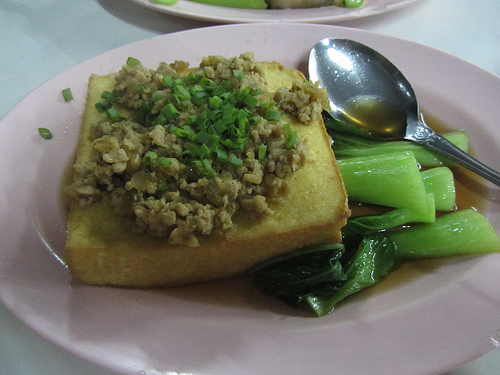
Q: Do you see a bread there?
A: Yes, there is a bread.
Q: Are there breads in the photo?
A: Yes, there is a bread.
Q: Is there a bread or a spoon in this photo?
A: Yes, there is a bread.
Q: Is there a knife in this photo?
A: No, there are no knives.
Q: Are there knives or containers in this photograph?
A: No, there are no knives or containers.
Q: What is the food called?
A: The food is a bread.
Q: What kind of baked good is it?
A: The food is a bread.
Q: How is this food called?
A: This is a bread.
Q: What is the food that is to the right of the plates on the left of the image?
A: The food is a bread.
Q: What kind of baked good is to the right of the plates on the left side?
A: The food is a bread.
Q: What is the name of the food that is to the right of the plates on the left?
A: The food is a bread.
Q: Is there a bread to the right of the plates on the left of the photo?
A: Yes, there is a bread to the right of the plates.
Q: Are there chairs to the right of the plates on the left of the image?
A: No, there is a bread to the right of the plates.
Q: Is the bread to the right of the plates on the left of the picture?
A: Yes, the bread is to the right of the plates.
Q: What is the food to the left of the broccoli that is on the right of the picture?
A: The food is a bread.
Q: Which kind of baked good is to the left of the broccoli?
A: The food is a bread.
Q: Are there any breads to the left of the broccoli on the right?
A: Yes, there is a bread to the left of the broccoli.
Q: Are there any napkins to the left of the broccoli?
A: No, there is a bread to the left of the broccoli.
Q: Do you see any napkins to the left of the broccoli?
A: No, there is a bread to the left of the broccoli.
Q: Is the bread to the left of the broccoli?
A: Yes, the bread is to the left of the broccoli.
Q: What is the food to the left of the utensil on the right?
A: The food is a bread.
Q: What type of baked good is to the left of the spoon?
A: The food is a bread.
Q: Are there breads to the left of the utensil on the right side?
A: Yes, there is a bread to the left of the spoon.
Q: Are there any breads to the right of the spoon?
A: No, the bread is to the left of the spoon.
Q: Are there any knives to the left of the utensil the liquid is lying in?
A: No, there is a bread to the left of the spoon.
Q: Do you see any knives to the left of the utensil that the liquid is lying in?
A: No, there is a bread to the left of the spoon.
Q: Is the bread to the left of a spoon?
A: Yes, the bread is to the left of a spoon.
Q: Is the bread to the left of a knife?
A: No, the bread is to the left of a spoon.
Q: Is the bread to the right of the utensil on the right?
A: No, the bread is to the left of the spoon.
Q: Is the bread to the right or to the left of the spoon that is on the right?
A: The bread is to the left of the spoon.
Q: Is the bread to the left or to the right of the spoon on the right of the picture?
A: The bread is to the left of the spoon.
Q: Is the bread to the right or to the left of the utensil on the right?
A: The bread is to the left of the spoon.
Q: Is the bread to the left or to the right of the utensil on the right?
A: The bread is to the left of the spoon.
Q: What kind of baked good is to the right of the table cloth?
A: The food is a bread.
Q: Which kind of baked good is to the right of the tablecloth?
A: The food is a bread.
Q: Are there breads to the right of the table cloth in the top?
A: Yes, there is a bread to the right of the tablecloth.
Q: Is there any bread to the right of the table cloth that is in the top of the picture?
A: Yes, there is a bread to the right of the tablecloth.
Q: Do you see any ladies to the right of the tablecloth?
A: No, there is a bread to the right of the tablecloth.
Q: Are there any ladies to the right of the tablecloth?
A: No, there is a bread to the right of the tablecloth.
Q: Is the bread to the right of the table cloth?
A: Yes, the bread is to the right of the table cloth.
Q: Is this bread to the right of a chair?
A: No, the bread is to the right of the table cloth.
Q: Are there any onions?
A: Yes, there are onions.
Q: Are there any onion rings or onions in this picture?
A: Yes, there are onions.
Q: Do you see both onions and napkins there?
A: No, there are onions but no napkins.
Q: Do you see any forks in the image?
A: No, there are no forks.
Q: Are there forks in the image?
A: No, there are no forks.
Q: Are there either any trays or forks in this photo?
A: No, there are no forks or trays.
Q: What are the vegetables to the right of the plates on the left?
A: The vegetables are onions.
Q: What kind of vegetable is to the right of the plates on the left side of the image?
A: The vegetables are onions.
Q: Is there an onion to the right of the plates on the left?
A: Yes, there are onions to the right of the plates.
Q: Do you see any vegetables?
A: Yes, there are vegetables.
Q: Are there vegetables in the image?
A: Yes, there are vegetables.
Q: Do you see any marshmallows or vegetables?
A: Yes, there are vegetables.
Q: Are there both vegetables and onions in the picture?
A: Yes, there are both vegetables and an onion.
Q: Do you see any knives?
A: No, there are no knives.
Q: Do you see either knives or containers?
A: No, there are no knives or containers.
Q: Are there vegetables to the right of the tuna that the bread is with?
A: Yes, there are vegetables to the right of the tuna.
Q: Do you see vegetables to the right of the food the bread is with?
A: Yes, there are vegetables to the right of the tuna.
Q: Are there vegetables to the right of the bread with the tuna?
A: Yes, there are vegetables to the right of the bread.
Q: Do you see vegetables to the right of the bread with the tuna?
A: Yes, there are vegetables to the right of the bread.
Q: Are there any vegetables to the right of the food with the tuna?
A: Yes, there are vegetables to the right of the bread.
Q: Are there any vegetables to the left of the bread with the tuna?
A: No, the vegetables are to the right of the bread.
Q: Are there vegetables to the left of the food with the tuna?
A: No, the vegetables are to the right of the bread.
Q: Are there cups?
A: No, there are no cups.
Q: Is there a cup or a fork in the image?
A: No, there are no cups or forks.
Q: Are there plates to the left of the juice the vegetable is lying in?
A: Yes, there are plates to the left of the juice.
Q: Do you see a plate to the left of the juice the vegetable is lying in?
A: Yes, there are plates to the left of the juice.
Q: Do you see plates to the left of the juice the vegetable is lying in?
A: Yes, there are plates to the left of the juice.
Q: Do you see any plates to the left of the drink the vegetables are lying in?
A: Yes, there are plates to the left of the juice.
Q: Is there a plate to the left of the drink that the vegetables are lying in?
A: Yes, there are plates to the left of the juice.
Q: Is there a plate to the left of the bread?
A: Yes, there are plates to the left of the bread.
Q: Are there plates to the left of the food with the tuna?
A: Yes, there are plates to the left of the bread.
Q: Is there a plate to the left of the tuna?
A: Yes, there are plates to the left of the tuna.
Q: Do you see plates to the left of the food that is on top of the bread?
A: Yes, there are plates to the left of the tuna.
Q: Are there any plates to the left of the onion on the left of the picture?
A: Yes, there are plates to the left of the onion.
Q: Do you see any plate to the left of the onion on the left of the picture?
A: Yes, there are plates to the left of the onion.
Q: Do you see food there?
A: Yes, there is food.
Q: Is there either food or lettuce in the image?
A: Yes, there is food.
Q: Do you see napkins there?
A: No, there are no napkins.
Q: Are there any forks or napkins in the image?
A: No, there are no napkins or forks.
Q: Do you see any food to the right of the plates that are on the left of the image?
A: Yes, there is food to the right of the plates.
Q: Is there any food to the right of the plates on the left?
A: Yes, there is food to the right of the plates.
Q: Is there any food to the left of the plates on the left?
A: No, the food is to the right of the plates.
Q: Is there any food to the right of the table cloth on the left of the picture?
A: Yes, there is food to the right of the tablecloth.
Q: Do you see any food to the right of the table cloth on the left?
A: Yes, there is food to the right of the tablecloth.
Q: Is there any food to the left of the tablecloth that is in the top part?
A: No, the food is to the right of the tablecloth.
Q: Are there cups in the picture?
A: No, there are no cups.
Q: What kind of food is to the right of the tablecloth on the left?
A: The food is tuna.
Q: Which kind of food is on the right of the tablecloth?
A: The food is tuna.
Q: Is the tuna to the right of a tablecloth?
A: Yes, the tuna is to the right of a tablecloth.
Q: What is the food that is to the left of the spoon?
A: The food is tuna.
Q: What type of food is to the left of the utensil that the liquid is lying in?
A: The food is tuna.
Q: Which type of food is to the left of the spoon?
A: The food is tuna.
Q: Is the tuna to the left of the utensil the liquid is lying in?
A: Yes, the tuna is to the left of the spoon.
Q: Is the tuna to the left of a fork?
A: No, the tuna is to the left of the spoon.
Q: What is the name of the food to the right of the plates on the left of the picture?
A: The food is tuna.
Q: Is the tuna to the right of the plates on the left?
A: Yes, the tuna is to the right of the plates.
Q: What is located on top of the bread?
A: The tuna is on top of the bread.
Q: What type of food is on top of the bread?
A: The food is tuna.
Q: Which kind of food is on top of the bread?
A: The food is tuna.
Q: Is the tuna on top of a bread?
A: Yes, the tuna is on top of a bread.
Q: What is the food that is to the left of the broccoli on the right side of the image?
A: The food is tuna.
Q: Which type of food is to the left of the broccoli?
A: The food is tuna.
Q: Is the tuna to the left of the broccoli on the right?
A: Yes, the tuna is to the left of the broccoli.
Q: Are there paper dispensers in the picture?
A: No, there are no paper dispensers.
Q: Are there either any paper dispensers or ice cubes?
A: No, there are no paper dispensers or ice cubes.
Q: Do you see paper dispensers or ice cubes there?
A: No, there are no paper dispensers or ice cubes.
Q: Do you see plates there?
A: Yes, there is a plate.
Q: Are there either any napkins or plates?
A: Yes, there is a plate.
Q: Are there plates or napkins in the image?
A: Yes, there is a plate.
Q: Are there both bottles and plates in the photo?
A: No, there is a plate but no bottles.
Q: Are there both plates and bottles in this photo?
A: No, there is a plate but no bottles.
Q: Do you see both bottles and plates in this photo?
A: No, there is a plate but no bottles.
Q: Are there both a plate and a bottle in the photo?
A: No, there is a plate but no bottles.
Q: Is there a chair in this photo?
A: No, there are no chairs.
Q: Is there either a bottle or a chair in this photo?
A: No, there are no chairs or bottles.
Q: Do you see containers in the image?
A: No, there are no containers.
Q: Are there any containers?
A: No, there are no containers.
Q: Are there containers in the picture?
A: No, there are no containers.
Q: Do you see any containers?
A: No, there are no containers.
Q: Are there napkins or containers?
A: No, there are no containers or napkins.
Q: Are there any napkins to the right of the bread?
A: No, there is a vegetable to the right of the bread.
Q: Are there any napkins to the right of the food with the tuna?
A: No, there is a vegetable to the right of the bread.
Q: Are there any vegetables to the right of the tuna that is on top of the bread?
A: Yes, there is a vegetable to the right of the tuna.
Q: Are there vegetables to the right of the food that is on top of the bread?
A: Yes, there is a vegetable to the right of the tuna.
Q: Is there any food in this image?
A: Yes, there is food.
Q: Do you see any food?
A: Yes, there is food.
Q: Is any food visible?
A: Yes, there is food.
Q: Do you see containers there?
A: No, there are no containers.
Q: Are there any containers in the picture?
A: No, there are no containers.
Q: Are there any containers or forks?
A: No, there are no containers or forks.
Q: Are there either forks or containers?
A: No, there are no containers or forks.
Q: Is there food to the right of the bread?
A: Yes, there is food to the right of the bread.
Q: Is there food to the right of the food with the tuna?
A: Yes, there is food to the right of the bread.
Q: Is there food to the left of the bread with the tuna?
A: No, the food is to the right of the bread.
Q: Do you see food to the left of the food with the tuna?
A: No, the food is to the right of the bread.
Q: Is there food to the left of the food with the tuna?
A: No, the food is to the right of the bread.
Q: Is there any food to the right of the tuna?
A: Yes, there is food to the right of the tuna.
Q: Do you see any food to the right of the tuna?
A: Yes, there is food to the right of the tuna.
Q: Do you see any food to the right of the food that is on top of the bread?
A: Yes, there is food to the right of the tuna.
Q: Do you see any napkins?
A: No, there are no napkins.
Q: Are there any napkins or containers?
A: No, there are no napkins or containers.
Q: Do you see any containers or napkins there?
A: No, there are no napkins or containers.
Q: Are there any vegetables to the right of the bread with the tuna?
A: Yes, there is a vegetable to the right of the bread.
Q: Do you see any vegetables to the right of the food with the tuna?
A: Yes, there is a vegetable to the right of the bread.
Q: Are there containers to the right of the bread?
A: No, there is a vegetable to the right of the bread.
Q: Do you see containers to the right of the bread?
A: No, there is a vegetable to the right of the bread.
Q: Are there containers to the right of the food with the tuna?
A: No, there is a vegetable to the right of the bread.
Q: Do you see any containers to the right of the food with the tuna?
A: No, there is a vegetable to the right of the bread.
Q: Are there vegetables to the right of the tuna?
A: Yes, there is a vegetable to the right of the tuna.